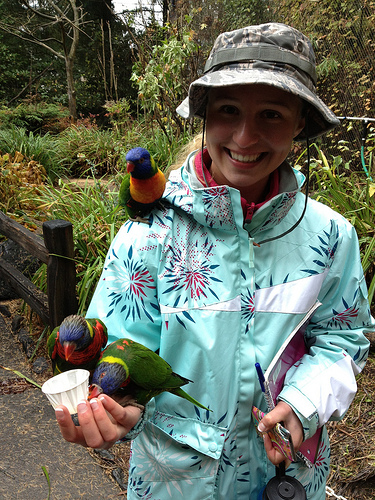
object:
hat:
[176, 22, 341, 142]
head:
[205, 23, 306, 188]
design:
[207, 286, 221, 303]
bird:
[119, 147, 166, 225]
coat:
[84, 145, 375, 499]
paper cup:
[42, 369, 91, 415]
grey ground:
[0, 298, 375, 500]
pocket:
[126, 407, 228, 498]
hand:
[54, 393, 141, 450]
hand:
[257, 401, 303, 471]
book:
[262, 298, 322, 469]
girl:
[53, 22, 375, 500]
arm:
[285, 215, 370, 423]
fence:
[0, 211, 78, 331]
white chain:
[324, 485, 348, 500]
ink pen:
[254, 362, 275, 413]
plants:
[129, 74, 172, 152]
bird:
[46, 314, 108, 381]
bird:
[87, 338, 214, 413]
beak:
[126, 160, 134, 173]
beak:
[63, 341, 77, 361]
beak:
[87, 383, 103, 399]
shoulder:
[110, 170, 205, 281]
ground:
[0, 125, 375, 500]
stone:
[0, 298, 126, 499]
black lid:
[264, 475, 307, 498]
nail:
[77, 401, 88, 412]